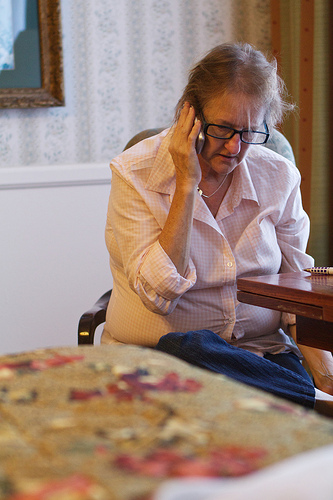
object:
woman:
[99, 43, 332, 418]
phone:
[193, 102, 204, 157]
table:
[235, 266, 333, 321]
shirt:
[101, 124, 315, 356]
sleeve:
[107, 162, 198, 317]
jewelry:
[197, 172, 229, 199]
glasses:
[195, 108, 271, 143]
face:
[199, 88, 265, 176]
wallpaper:
[0, 1, 273, 164]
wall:
[2, 2, 271, 344]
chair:
[77, 126, 298, 347]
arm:
[77, 286, 111, 347]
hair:
[172, 41, 296, 128]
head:
[196, 48, 268, 175]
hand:
[168, 100, 203, 184]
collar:
[144, 119, 260, 228]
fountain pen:
[303, 265, 331, 276]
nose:
[224, 132, 241, 154]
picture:
[1, 1, 44, 89]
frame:
[1, 0, 67, 112]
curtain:
[271, 0, 333, 267]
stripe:
[299, 2, 311, 216]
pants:
[157, 328, 312, 410]